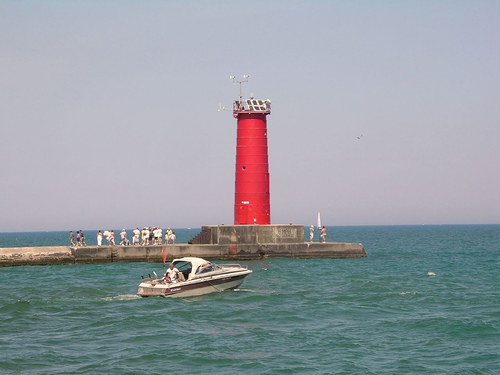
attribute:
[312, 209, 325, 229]
object — white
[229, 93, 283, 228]
lighthouse — red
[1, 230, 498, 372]
water — buoyant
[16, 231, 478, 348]
water — blue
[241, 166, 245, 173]
circle — black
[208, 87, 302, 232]
tower — red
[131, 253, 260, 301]
boat — white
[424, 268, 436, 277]
buoy — white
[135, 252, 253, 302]
boat — brown, white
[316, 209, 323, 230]
sailboat — white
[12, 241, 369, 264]
pier — cement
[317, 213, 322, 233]
sail — white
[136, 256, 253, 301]
boat — white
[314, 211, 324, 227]
sail — white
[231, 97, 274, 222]
lighthouse — red